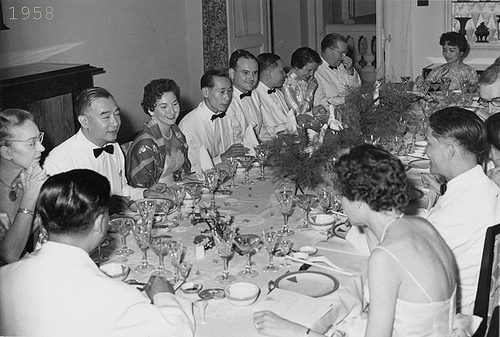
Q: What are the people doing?
A: Having dinner.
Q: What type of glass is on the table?
A: Wine glasses.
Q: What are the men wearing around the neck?
A: Bow ties.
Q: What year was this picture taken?
A: 1958.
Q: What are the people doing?
A: Eating.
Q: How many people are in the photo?
A: Fourteen.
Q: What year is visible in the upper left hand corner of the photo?
A: 1958.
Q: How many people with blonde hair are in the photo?
A: Two.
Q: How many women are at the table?
A: Five.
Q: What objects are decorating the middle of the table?
A: Plants.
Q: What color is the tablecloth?
A: White.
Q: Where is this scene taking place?
A: In a dining hall.